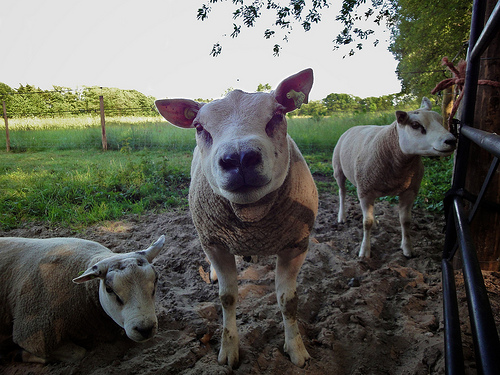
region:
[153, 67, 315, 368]
Sheep standing in the middle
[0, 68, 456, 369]
Group of three sheep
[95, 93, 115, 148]
Brown fence post in the field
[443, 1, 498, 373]
Black metal fence gate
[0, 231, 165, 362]
Sheep that's lying down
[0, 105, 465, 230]
Green grassy field behind sheep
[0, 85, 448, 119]
Trees behind the sheep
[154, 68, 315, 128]
Ears of middle sheep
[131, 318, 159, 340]
Nose on the sheep that's lying down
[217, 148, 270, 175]
Nose of middle sheep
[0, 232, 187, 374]
this is a sheep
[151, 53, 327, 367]
this is a sheep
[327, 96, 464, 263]
this is a sheep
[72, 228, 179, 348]
the head of a sheep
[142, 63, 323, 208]
the head of a sheep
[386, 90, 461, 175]
the head of a sheep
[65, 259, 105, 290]
the ear of a sheep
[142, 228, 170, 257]
the ear of a sheep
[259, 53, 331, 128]
the ear of a sheep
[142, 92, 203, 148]
the ear of a sheep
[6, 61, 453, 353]
The sheep are white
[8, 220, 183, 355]
The sheep is lying down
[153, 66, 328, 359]
The sheep is standing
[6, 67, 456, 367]
The sheep are on sand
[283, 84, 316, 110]
The tag is yellow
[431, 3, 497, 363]
The gate is black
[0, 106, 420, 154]
Tall grass behind the fence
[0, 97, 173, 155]
The fence has brown posts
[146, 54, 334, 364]
The sheep is facing the camera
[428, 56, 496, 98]
The rope is red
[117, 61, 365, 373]
animal standing on the mud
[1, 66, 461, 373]
group of three animals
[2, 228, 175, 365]
animal laying in the mud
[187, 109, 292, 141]
eyes on either side of the head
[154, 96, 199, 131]
inside of the ear is pink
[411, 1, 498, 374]
large black iron fence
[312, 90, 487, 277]
animal looking at the fence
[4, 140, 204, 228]
green grass on the ground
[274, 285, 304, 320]
mud on the leg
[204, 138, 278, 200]
large black snout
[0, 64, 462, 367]
three sheep in the shade of a tree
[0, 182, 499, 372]
rich chocolate brown earth by a gate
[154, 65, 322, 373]
a sheep with a black nose a pink ears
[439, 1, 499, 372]
a black railed metal gate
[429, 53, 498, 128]
a red rope holding a gate closed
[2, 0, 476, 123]
bright green lush trees around a pasture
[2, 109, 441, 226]
a field of tall green soft looking grass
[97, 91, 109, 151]
a brown wooden fence post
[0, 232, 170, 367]
a sheep with short hair resting in the shade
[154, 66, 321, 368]
a sheep with a pale yellow tag in each ear